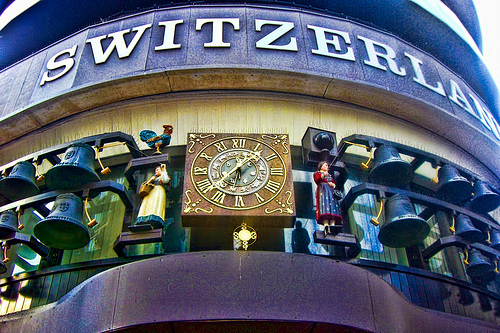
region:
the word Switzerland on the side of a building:
[42, 16, 497, 127]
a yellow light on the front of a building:
[232, 214, 259, 243]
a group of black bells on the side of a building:
[368, 139, 495, 281]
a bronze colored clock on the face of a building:
[172, 124, 303, 243]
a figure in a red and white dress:
[310, 158, 340, 234]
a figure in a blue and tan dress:
[125, 158, 174, 241]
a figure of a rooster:
[136, 121, 176, 153]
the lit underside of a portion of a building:
[148, 98, 414, 153]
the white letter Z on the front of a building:
[244, 15, 299, 69]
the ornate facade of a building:
[3, 18, 488, 327]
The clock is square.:
[172, 122, 299, 233]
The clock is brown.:
[173, 122, 303, 232]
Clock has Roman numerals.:
[177, 121, 303, 233]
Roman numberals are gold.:
[160, 118, 307, 235]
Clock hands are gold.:
[171, 122, 304, 237]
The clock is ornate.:
[169, 115, 299, 237]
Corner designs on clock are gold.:
[172, 123, 307, 239]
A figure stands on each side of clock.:
[98, 115, 355, 265]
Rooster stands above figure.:
[111, 112, 186, 261]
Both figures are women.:
[111, 125, 354, 255]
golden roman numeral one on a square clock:
[252, 140, 262, 152]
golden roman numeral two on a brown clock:
[263, 150, 281, 162]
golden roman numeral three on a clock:
[270, 165, 285, 175]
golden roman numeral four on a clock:
[251, 193, 269, 205]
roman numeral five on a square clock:
[232, 193, 247, 204]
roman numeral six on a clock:
[206, 190, 226, 202]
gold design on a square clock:
[183, 184, 214, 214]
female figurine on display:
[311, 159, 358, 238]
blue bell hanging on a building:
[371, 188, 434, 251]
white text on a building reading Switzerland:
[37, 16, 499, 140]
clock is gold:
[162, 127, 306, 222]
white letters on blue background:
[25, 40, 448, 103]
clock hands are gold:
[200, 152, 265, 190]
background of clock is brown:
[183, 131, 286, 216]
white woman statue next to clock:
[122, 165, 177, 227]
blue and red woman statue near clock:
[307, 160, 347, 247]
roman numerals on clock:
[210, 131, 269, 193]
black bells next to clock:
[25, 192, 103, 252]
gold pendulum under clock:
[227, 217, 272, 254]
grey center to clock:
[209, 156, 271, 186]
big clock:
[158, 91, 296, 206]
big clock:
[185, 155, 333, 322]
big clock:
[211, 140, 291, 272]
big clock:
[134, 48, 342, 275]